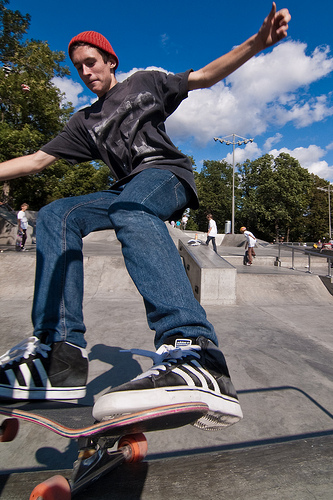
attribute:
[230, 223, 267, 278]
boy — with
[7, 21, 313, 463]
boy — young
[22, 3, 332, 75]
sky — clear, blue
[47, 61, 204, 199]
tshirt — black, gray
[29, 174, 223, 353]
jeans — blue, denim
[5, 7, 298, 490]
man — young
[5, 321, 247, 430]
sneakers — black, white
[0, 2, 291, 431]
boy — teenage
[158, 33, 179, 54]
cloud — white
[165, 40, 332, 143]
cloud — white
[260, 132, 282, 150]
cloud — white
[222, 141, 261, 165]
cloud — white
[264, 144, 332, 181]
cloud — white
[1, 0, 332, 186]
sky — blue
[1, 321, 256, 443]
sneakers — black, white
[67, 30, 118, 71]
hat — short, red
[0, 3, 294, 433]
man — young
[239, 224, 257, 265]
man — young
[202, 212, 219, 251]
man — young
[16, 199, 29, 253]
man — young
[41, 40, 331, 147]
clouds — large, white